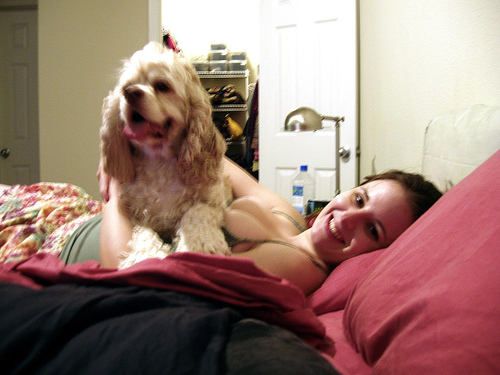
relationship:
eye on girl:
[365, 220, 382, 242] [0, 170, 442, 294]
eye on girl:
[354, 190, 365, 210] [0, 170, 442, 294]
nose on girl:
[319, 202, 372, 231] [20, 158, 447, 302]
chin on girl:
[310, 219, 338, 263] [245, 153, 483, 260]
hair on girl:
[398, 170, 440, 206] [302, 171, 421, 300]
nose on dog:
[120, 81, 144, 103] [73, 28, 308, 270]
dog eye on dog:
[152, 78, 176, 93] [98, 38, 232, 271]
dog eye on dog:
[122, 82, 129, 88] [98, 38, 232, 271]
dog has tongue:
[97, 41, 232, 272] [122, 113, 147, 140]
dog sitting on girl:
[97, 41, 232, 272] [0, 153, 444, 298]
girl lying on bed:
[0, 153, 444, 298] [388, 160, 498, 371]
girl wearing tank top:
[0, 153, 444, 298] [70, 207, 101, 258]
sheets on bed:
[0, 249, 339, 354] [0, 152, 498, 372]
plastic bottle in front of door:
[265, 157, 317, 217] [243, 0, 362, 230]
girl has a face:
[0, 153, 444, 298] [295, 166, 417, 254]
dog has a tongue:
[98, 38, 232, 271] [117, 118, 167, 140]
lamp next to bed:
[278, 104, 343, 193] [0, 175, 499, 369]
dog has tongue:
[97, 41, 232, 272] [121, 110, 171, 143]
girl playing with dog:
[0, 153, 444, 298] [84, 41, 241, 271]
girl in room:
[0, 153, 444, 298] [1, 4, 499, 374]